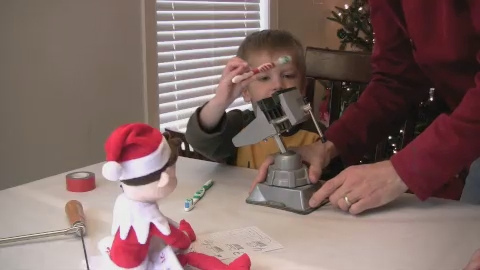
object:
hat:
[101, 122, 172, 182]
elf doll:
[97, 122, 251, 269]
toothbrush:
[184, 177, 214, 212]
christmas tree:
[317, 0, 471, 201]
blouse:
[322, 0, 480, 202]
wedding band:
[343, 194, 352, 207]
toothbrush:
[232, 55, 293, 85]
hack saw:
[0, 199, 98, 270]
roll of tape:
[65, 170, 96, 193]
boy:
[185, 27, 347, 181]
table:
[0, 154, 479, 269]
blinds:
[156, 0, 262, 152]